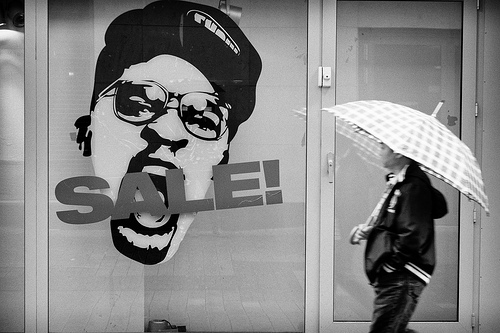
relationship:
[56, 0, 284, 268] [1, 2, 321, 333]
sign on wall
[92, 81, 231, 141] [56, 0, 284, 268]
glasses are on sign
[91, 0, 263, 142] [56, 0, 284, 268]
hat on sign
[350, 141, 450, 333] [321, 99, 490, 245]
person has umbrella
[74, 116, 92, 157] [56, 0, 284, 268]
ear on sign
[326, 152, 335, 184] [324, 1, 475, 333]
knob on door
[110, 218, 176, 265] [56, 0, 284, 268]
beard on sign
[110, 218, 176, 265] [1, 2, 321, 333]
beard on glass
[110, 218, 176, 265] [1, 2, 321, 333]
beard on wall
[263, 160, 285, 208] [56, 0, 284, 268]
exclamation mark on sign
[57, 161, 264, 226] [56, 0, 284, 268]
letters are on sign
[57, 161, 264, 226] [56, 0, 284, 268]
letters on sign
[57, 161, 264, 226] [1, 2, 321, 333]
letters are on wall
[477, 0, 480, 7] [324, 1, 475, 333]
hinge on door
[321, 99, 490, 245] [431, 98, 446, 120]
umbrella has tip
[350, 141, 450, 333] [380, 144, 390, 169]
person has face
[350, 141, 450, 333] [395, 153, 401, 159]
person has ear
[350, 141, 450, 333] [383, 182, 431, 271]
person has arm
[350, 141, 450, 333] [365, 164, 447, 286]
person has jacket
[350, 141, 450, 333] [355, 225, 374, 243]
person has hand